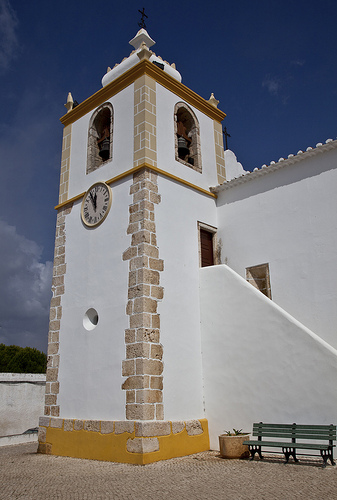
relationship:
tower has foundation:
[46, 8, 233, 424] [40, 419, 214, 466]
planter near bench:
[217, 428, 251, 459] [246, 423, 336, 468]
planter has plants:
[217, 428, 251, 459] [226, 429, 247, 437]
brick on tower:
[132, 79, 157, 413] [46, 8, 233, 424]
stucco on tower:
[68, 230, 126, 415] [46, 8, 233, 424]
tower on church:
[46, 8, 233, 424] [54, 7, 331, 466]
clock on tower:
[77, 181, 116, 229] [46, 8, 233, 424]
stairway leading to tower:
[201, 222, 336, 423] [46, 8, 233, 424]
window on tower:
[81, 103, 117, 169] [46, 8, 233, 424]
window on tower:
[173, 99, 204, 170] [46, 8, 233, 424]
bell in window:
[96, 131, 113, 156] [81, 103, 117, 169]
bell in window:
[178, 123, 190, 151] [173, 99, 204, 170]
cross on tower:
[134, 4, 152, 32] [46, 8, 233, 424]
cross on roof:
[220, 124, 234, 154] [221, 127, 255, 192]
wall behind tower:
[220, 165, 335, 319] [46, 8, 233, 424]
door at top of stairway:
[200, 226, 217, 269] [201, 222, 336, 423]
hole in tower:
[80, 307, 100, 332] [46, 8, 233, 424]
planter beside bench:
[217, 428, 251, 459] [246, 423, 336, 468]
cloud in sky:
[6, 225, 50, 326] [2, 2, 336, 128]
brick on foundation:
[39, 421, 198, 437] [40, 419, 214, 466]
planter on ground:
[217, 428, 251, 459] [75, 460, 335, 497]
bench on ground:
[246, 423, 336, 468] [75, 460, 335, 497]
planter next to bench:
[217, 428, 251, 459] [246, 423, 336, 468]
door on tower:
[200, 226, 217, 269] [46, 8, 233, 424]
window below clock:
[80, 307, 100, 332] [77, 181, 116, 229]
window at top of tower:
[81, 103, 117, 169] [46, 8, 233, 424]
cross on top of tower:
[134, 4, 152, 32] [46, 8, 233, 424]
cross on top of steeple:
[134, 4, 152, 32] [96, 28, 186, 77]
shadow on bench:
[248, 455, 330, 467] [246, 423, 336, 468]